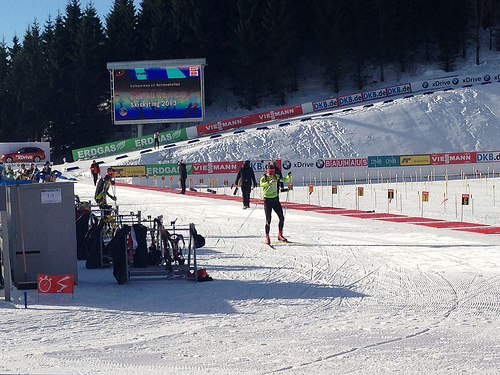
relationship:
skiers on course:
[205, 157, 299, 235] [49, 39, 494, 315]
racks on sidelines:
[114, 220, 194, 273] [123, 183, 261, 224]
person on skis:
[244, 157, 293, 209] [258, 213, 310, 263]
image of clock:
[25, 273, 78, 293] [35, 275, 57, 303]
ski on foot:
[250, 213, 284, 279] [264, 218, 276, 238]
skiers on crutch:
[205, 157, 299, 235] [107, 175, 127, 202]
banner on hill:
[62, 139, 116, 161] [124, 79, 435, 139]